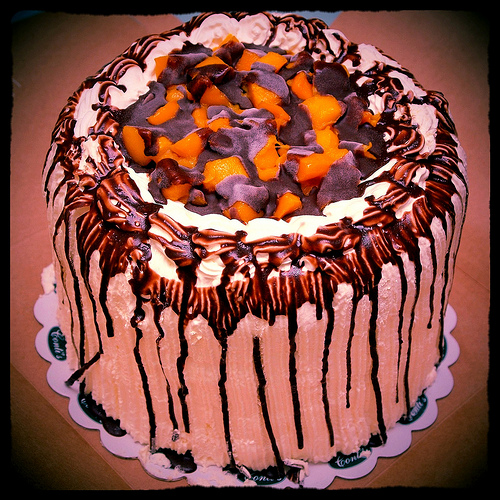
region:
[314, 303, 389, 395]
this is a cake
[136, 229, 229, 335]
this is a cake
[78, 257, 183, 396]
this is a cake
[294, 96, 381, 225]
this is a cake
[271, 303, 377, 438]
this is a cake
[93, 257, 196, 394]
this is a cake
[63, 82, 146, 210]
this is a cake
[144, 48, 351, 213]
brown icing on cake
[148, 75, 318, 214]
orange icing on cake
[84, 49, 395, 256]
chocolate sauce on white icing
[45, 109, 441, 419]
chocolate sauce on side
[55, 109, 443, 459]
white base on brown table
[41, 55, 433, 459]
white ice cream cake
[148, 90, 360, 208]
slices of mango on top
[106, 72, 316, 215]
slices of mango on top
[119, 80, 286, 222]
slices of mango on top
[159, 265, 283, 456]
lines of chocolate syrup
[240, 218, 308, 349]
lines of chocolate syrup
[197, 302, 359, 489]
lines of chocolate syrup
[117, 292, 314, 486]
lines of chocolate syrup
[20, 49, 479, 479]
This is a cake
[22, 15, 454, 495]
The cake only has one tier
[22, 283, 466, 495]
The cake is sitting on paper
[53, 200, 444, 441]
There is chocolate syrup on the cake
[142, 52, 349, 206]
There is fruit on top of the cake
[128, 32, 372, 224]
There fruit is orange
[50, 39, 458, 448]
The cake is covered in cream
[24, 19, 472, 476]
None of the cake has been eaten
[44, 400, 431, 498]
The cake is near the edge of the countertop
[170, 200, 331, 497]
Section of a cake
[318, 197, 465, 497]
Section of a cake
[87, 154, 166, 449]
Section of a cake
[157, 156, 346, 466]
Section of a cake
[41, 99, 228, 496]
Section of a cake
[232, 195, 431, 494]
Section of a cake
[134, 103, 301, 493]
Section of a cake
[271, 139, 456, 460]
Section of a cake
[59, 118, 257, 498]
Section of a cake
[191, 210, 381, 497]
Section of a cake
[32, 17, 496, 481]
drizzles on the cake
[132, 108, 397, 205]
The cake has purple icing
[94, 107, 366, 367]
The cake has orange icing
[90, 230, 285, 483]
The icing is white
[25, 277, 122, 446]
The cardboard is white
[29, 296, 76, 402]
A black circle on the cardboard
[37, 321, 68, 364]
The black circle has white letter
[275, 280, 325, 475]
The chocolate is falling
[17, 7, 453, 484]
The cake is round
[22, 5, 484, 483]
The cake is tall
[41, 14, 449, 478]
big cake with chocolate syrup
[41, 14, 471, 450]
chocolate syrup on big cake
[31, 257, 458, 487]
white round plate under cake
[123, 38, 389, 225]
dark and oranges on top of cake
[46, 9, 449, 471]
cake on top of brown wooden table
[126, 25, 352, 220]
orange sliced food on top of cake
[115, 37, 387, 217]
sliced dark chocolate on top of cake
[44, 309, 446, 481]
black syrup under cake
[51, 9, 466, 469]
tall cake with chocolate and orange food on top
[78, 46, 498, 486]
a cake on the aboard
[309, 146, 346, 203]
a chocolate shaving on top